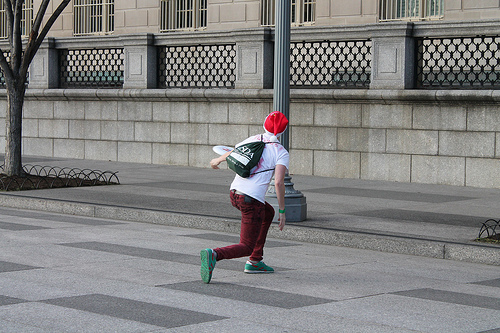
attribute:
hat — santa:
[262, 102, 291, 145]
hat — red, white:
[262, 107, 288, 146]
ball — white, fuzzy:
[266, 133, 279, 143]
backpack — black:
[222, 129, 285, 179]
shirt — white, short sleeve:
[234, 130, 290, 204]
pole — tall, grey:
[270, 2, 308, 223]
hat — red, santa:
[262, 109, 289, 144]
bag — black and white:
[224, 127, 261, 177]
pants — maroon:
[195, 179, 289, 279]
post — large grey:
[254, 15, 326, 218]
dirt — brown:
[13, 146, 78, 196]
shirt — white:
[220, 125, 304, 244]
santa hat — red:
[257, 102, 296, 133]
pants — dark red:
[219, 186, 277, 286]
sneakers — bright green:
[184, 244, 292, 284]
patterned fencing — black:
[85, 22, 456, 121]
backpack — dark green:
[221, 128, 270, 178]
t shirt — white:
[224, 123, 284, 210]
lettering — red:
[244, 136, 281, 174]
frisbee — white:
[264, 190, 292, 226]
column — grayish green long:
[259, 17, 295, 147]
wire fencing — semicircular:
[31, 150, 128, 196]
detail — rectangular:
[123, 46, 147, 76]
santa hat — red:
[261, 109, 290, 139]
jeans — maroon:
[198, 181, 299, 295]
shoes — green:
[188, 247, 275, 278]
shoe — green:
[165, 240, 285, 284]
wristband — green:
[278, 192, 304, 212]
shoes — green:
[189, 238, 269, 305]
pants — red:
[214, 182, 316, 258]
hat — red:
[238, 93, 305, 146]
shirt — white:
[216, 118, 303, 213]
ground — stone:
[31, 216, 253, 318]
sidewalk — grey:
[31, 227, 253, 330]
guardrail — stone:
[303, 11, 481, 79]